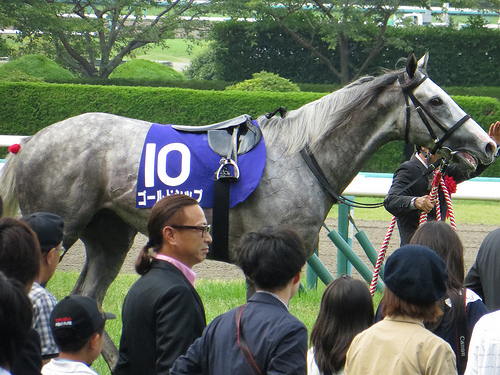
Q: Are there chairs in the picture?
A: No, there are no chairs.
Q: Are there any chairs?
A: No, there are no chairs.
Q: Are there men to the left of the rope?
A: Yes, there is a man to the left of the rope.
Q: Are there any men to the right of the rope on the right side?
A: No, the man is to the left of the rope.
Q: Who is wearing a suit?
A: The man is wearing a suit.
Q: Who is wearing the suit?
A: The man is wearing a suit.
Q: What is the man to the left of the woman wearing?
A: The man is wearing a suit.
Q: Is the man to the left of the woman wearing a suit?
A: Yes, the man is wearing a suit.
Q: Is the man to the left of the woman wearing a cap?
A: No, the man is wearing a suit.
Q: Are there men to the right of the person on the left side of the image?
A: Yes, there is a man to the right of the person.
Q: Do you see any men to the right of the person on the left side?
A: Yes, there is a man to the right of the person.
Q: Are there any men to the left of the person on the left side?
A: No, the man is to the right of the person.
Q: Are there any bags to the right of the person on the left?
A: No, there is a man to the right of the person.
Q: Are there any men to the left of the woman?
A: Yes, there is a man to the left of the woman.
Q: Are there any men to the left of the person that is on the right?
A: Yes, there is a man to the left of the woman.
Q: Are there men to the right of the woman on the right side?
A: No, the man is to the left of the woman.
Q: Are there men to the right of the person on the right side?
A: No, the man is to the left of the woman.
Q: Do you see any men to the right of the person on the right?
A: No, the man is to the left of the woman.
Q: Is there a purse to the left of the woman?
A: No, there is a man to the left of the woman.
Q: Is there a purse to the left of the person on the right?
A: No, there is a man to the left of the woman.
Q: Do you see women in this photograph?
A: Yes, there is a woman.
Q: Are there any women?
A: Yes, there is a woman.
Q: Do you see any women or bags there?
A: Yes, there is a woman.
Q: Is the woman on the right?
A: Yes, the woman is on the right of the image.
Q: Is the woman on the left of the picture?
A: No, the woman is on the right of the image.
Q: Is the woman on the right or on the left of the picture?
A: The woman is on the right of the image.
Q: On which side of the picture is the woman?
A: The woman is on the right of the image.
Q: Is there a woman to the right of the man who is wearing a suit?
A: Yes, there is a woman to the right of the man.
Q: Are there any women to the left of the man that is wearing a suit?
A: No, the woman is to the right of the man.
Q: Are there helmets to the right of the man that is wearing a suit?
A: No, there is a woman to the right of the man.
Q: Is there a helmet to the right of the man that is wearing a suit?
A: No, there is a woman to the right of the man.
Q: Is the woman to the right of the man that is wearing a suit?
A: Yes, the woman is to the right of the man.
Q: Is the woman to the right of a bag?
A: No, the woman is to the right of the man.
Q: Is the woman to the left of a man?
A: No, the woman is to the right of a man.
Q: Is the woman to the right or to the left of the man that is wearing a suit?
A: The woman is to the right of the man.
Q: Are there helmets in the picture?
A: No, there are no helmets.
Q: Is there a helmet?
A: No, there are no helmets.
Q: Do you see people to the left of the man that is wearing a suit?
A: Yes, there is a person to the left of the man.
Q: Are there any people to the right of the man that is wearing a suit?
A: No, the person is to the left of the man.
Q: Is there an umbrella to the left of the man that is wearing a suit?
A: No, there is a person to the left of the man.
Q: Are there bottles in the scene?
A: No, there are no bottles.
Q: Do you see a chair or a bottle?
A: No, there are no bottles or chairs.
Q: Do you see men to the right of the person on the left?
A: Yes, there is a man to the right of the person.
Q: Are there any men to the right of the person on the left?
A: Yes, there is a man to the right of the person.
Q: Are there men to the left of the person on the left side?
A: No, the man is to the right of the person.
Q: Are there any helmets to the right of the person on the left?
A: No, there is a man to the right of the person.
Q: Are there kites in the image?
A: No, there are no kites.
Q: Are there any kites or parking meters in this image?
A: No, there are no kites or parking meters.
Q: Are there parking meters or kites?
A: No, there are no kites or parking meters.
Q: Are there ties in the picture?
A: No, there are no ties.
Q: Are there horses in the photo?
A: Yes, there is a horse.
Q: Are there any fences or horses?
A: Yes, there is a horse.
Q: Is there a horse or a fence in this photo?
A: Yes, there is a horse.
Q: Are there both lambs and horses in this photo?
A: No, there is a horse but no lambs.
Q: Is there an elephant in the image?
A: No, there are no elephants.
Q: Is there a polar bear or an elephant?
A: No, there are no elephants or polar bears.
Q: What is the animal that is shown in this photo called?
A: The animal is a horse.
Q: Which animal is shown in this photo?
A: The animal is a horse.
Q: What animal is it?
A: The animal is a horse.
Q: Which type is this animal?
A: That is a horse.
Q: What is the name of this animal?
A: That is a horse.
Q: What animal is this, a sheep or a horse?
A: That is a horse.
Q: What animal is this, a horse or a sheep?
A: That is a horse.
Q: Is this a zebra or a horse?
A: This is a horse.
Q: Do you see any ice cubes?
A: No, there are no ice cubes.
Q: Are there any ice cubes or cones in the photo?
A: No, there are no ice cubes or cones.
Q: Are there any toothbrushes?
A: No, there are no toothbrushes.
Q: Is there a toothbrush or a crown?
A: No, there are no toothbrushes or crowns.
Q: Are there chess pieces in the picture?
A: No, there are no chess pieces.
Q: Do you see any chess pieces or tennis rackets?
A: No, there are no chess pieces or tennis rackets.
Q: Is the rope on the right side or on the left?
A: The rope is on the right of the image.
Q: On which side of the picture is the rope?
A: The rope is on the right of the image.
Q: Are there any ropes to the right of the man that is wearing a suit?
A: Yes, there is a rope to the right of the man.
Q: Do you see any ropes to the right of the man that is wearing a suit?
A: Yes, there is a rope to the right of the man.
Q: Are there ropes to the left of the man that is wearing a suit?
A: No, the rope is to the right of the man.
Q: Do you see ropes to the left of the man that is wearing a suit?
A: No, the rope is to the right of the man.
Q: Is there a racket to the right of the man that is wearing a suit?
A: No, there is a rope to the right of the man.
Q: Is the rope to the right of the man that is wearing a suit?
A: Yes, the rope is to the right of the man.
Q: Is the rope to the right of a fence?
A: No, the rope is to the right of the man.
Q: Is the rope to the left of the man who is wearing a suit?
A: No, the rope is to the right of the man.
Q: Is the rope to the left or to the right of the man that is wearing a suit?
A: The rope is to the right of the man.